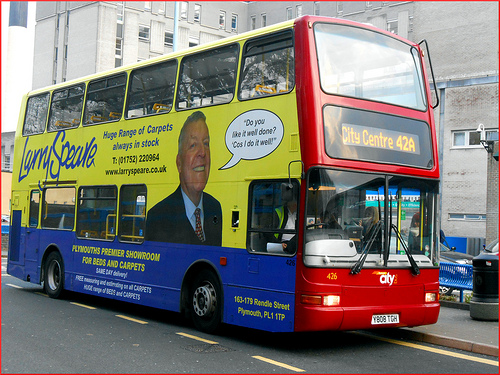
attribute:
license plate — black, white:
[368, 313, 401, 326]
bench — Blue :
[443, 258, 474, 293]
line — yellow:
[249, 350, 310, 373]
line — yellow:
[172, 324, 219, 347]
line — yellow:
[112, 310, 152, 329]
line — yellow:
[68, 293, 103, 315]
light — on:
[309, 282, 441, 327]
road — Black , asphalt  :
[4, 287, 492, 373]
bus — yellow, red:
[9, 15, 441, 337]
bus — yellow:
[12, 6, 462, 357]